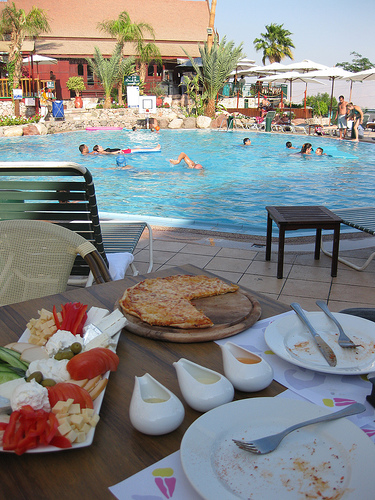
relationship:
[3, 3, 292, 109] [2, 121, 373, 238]
palm trees surrounding pool